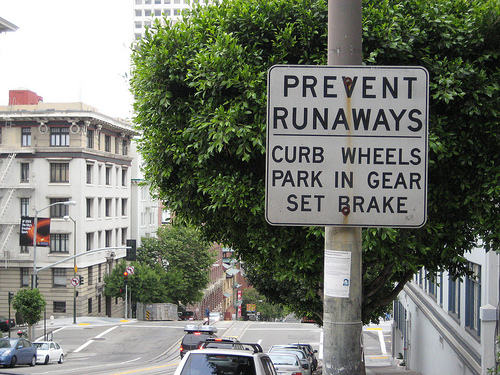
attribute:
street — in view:
[0, 311, 393, 374]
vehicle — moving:
[179, 323, 219, 363]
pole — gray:
[320, 1, 364, 375]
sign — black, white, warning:
[264, 62, 430, 229]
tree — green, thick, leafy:
[129, 0, 499, 374]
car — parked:
[32, 339, 68, 367]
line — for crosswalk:
[33, 322, 119, 354]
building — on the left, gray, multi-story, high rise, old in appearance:
[0, 89, 145, 319]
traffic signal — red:
[123, 269, 129, 286]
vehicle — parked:
[173, 338, 280, 374]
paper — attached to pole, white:
[324, 249, 352, 299]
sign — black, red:
[125, 264, 136, 278]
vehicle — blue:
[0, 337, 38, 369]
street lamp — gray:
[37, 199, 77, 213]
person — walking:
[201, 306, 211, 327]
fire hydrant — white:
[49, 315, 55, 327]